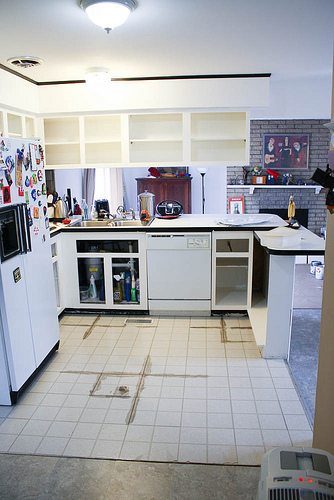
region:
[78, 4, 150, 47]
Light on the ceiling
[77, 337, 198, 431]
The tile is messed up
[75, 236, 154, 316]
Cabinets on the bottom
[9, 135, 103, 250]
magnets on the fridge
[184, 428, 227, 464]
Grout between the tiles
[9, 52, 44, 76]
Water sprayer on ceiling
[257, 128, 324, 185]
Art on the wall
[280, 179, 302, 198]
Bricks around fire place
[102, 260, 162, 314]
Cleaning products in cabinet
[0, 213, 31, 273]
Ice dispenser on fridge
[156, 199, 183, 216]
a portable radio on a kitchen counter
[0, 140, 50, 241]
refrigerator's magnets on a fridge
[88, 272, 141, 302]
various bottle underneath the sink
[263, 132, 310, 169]
a painting on a brick wall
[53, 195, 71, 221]
a black and silver kettle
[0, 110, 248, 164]
empty white cabinets in a kitchen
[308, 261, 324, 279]
pots of paints on the floor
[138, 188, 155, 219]
a silver pot on a counter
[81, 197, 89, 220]
dish washing liquid on a counter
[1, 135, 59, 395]
a white fridge in a kitchen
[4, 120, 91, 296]
a refrigerator in a kitchen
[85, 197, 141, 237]
a fosset in a kitchen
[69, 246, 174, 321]
a cabinet in a kitchen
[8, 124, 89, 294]
a white refrigerator in a kitchen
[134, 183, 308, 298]
a countertop in a kitchen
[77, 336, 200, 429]
tile on a floor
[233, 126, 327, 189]
a picture on a wall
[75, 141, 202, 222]
a window in a kitchen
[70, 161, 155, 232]
curtains in a kitchen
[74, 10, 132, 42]
a light in a kitchen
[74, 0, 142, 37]
A light fixture on the ceiling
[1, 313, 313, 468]
Beige tiles on the floor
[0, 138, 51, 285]
Many magnets on the fridge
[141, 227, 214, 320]
A dishwasher is white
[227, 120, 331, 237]
Bricks on a wall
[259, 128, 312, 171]
A painting hanging on the wall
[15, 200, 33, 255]
Two black handles of a fridge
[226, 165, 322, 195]
Items on a mantle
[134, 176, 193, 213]
A brown wooden cabinet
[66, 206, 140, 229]
A faucet over a double sink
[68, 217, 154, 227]
stainless steel kitchen sink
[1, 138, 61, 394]
white refrigerator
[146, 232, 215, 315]
white dishwasher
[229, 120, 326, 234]
gray brick fireplace beyond kitchen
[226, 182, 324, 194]
white wood mantel on the fireplace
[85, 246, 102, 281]
silver garbage disposal under sink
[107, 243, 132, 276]
white pipes under sink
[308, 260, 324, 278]
paint cans in living room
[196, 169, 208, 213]
floor lamp in the living room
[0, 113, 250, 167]
empty white upper cabinets